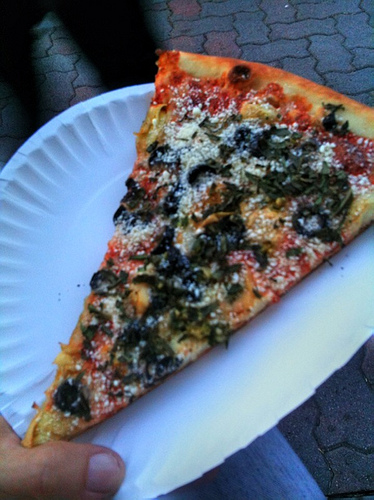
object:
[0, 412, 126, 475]
hand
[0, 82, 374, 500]
plate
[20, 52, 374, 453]
pizza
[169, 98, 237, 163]
cheese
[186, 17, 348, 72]
ground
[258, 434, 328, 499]
jeans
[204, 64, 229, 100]
sauce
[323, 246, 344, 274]
crumbs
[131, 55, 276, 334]
slice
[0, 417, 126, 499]
thumb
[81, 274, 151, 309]
olive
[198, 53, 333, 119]
crust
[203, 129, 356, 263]
herbs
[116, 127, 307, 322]
toppings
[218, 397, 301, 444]
edge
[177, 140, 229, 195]
parmesan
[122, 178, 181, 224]
olives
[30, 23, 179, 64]
shadows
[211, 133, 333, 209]
spinach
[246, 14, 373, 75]
bricks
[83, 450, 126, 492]
nail